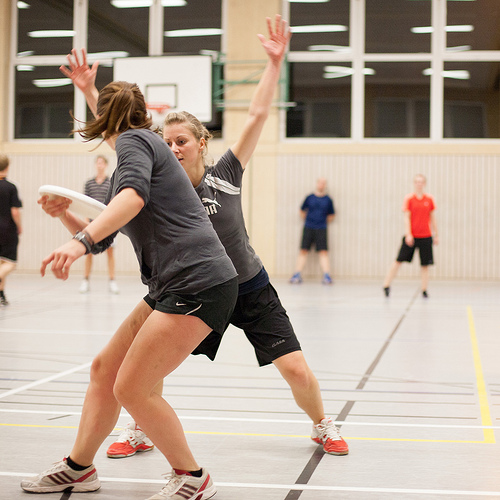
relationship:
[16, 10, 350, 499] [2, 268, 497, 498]
two girls playing frisbee on court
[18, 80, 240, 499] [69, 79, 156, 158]
girl has brown hair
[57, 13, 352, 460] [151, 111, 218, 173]
girl has blond hair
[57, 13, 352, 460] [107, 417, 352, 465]
girl has red shoes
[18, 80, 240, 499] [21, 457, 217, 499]
girl has light colored shoes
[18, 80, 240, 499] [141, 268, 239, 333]
girl has short black shorts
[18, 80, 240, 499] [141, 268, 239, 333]
girl has on pair of black shorts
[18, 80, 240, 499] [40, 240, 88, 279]
girl lowers her left hand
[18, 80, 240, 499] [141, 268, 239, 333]
girl wearing short black shorts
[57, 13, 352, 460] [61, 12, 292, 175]
girl has her hands extended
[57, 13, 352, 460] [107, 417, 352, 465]
girl has on red shoes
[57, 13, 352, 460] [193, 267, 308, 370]
girl wearing black shorts